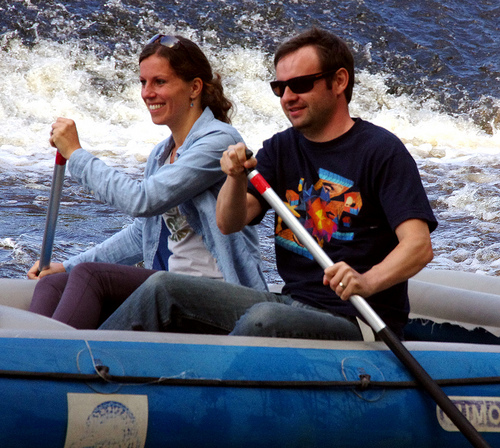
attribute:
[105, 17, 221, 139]
woman — smiling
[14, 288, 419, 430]
boat — blue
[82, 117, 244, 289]
blazer — blue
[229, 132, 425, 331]
tshirt — black